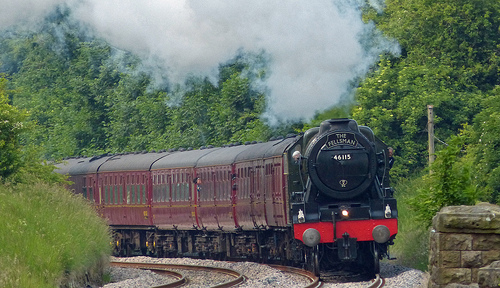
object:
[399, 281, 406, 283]
stone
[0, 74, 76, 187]
trees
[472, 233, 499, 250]
brick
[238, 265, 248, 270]
stone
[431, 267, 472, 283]
stone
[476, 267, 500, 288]
stone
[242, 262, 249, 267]
stone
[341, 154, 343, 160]
white number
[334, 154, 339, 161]
number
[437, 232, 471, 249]
brick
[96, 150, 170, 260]
train cars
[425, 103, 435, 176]
pole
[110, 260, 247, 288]
train track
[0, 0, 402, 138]
smoke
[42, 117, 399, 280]
train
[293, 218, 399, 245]
bottom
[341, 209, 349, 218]
light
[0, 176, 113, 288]
grass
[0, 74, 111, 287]
hill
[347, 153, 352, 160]
numbers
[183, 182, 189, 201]
window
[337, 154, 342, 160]
numbers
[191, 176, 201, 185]
head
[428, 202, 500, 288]
wall